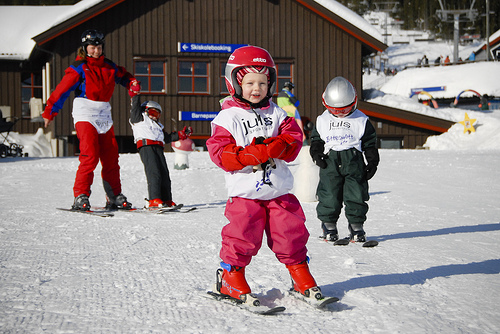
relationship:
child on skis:
[205, 45, 326, 306] [190, 286, 338, 316]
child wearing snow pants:
[205, 45, 326, 306] [218, 192, 311, 265]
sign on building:
[177, 41, 250, 53] [1, 0, 459, 157]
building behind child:
[1, 0, 459, 157] [205, 45, 326, 306]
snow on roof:
[1, 0, 383, 60] [1, 1, 390, 73]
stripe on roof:
[36, 1, 382, 54] [1, 1, 390, 73]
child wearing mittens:
[205, 45, 326, 306] [222, 132, 298, 172]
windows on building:
[133, 61, 295, 96] [1, 0, 459, 157]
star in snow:
[457, 114, 477, 134] [0, 1, 499, 333]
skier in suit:
[309, 77, 380, 248] [309, 108, 381, 234]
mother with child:
[41, 29, 142, 212] [129, 83, 193, 210]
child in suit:
[205, 45, 326, 306] [205, 96, 310, 266]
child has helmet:
[205, 45, 326, 306] [225, 47, 277, 110]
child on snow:
[205, 45, 326, 306] [0, 1, 499, 333]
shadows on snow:
[137, 191, 500, 317] [0, 1, 499, 333]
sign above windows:
[177, 41, 250, 53] [133, 61, 295, 96]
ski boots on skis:
[216, 256, 318, 303] [190, 286, 338, 316]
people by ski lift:
[387, 50, 476, 76] [369, 1, 495, 72]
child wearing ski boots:
[205, 45, 326, 306] [216, 256, 318, 303]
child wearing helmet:
[205, 45, 326, 306] [225, 47, 277, 110]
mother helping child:
[41, 29, 142, 212] [129, 83, 193, 210]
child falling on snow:
[129, 83, 193, 210] [0, 1, 499, 333]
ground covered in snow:
[1, 12, 500, 333] [0, 1, 499, 333]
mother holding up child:
[41, 29, 142, 212] [129, 83, 193, 210]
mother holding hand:
[41, 29, 142, 212] [129, 81, 142, 96]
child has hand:
[129, 83, 193, 210] [129, 81, 142, 96]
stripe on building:
[36, 1, 382, 54] [1, 0, 459, 157]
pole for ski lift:
[453, 15, 460, 65] [369, 1, 495, 72]